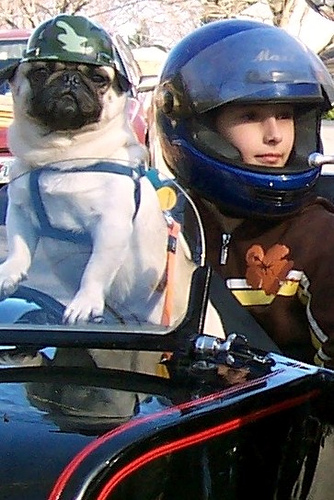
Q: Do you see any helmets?
A: Yes, there is a helmet.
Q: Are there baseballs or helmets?
A: Yes, there is a helmet.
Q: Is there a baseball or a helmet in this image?
A: Yes, there is a helmet.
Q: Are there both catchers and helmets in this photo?
A: No, there is a helmet but no catchers.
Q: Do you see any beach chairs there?
A: No, there are no beach chairs.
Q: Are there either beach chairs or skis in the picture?
A: No, there are no beach chairs or skis.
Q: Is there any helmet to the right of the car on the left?
A: Yes, there is a helmet to the right of the car.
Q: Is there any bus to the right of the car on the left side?
A: No, there is a helmet to the right of the car.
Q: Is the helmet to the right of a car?
A: Yes, the helmet is to the right of a car.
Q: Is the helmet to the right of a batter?
A: No, the helmet is to the right of a car.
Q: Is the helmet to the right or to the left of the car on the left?
A: The helmet is to the right of the car.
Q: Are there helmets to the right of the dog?
A: Yes, there is a helmet to the right of the dog.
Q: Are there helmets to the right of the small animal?
A: Yes, there is a helmet to the right of the dog.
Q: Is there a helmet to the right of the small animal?
A: Yes, there is a helmet to the right of the dog.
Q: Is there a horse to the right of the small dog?
A: No, there is a helmet to the right of the dog.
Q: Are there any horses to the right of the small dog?
A: No, there is a helmet to the right of the dog.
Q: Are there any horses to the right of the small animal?
A: No, there is a helmet to the right of the dog.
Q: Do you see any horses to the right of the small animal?
A: No, there is a helmet to the right of the dog.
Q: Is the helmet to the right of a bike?
A: No, the helmet is to the right of the dog.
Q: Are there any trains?
A: No, there are no trains.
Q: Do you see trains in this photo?
A: No, there are no trains.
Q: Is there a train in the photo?
A: No, there are no trains.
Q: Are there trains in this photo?
A: No, there are no trains.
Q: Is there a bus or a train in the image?
A: No, there are no trains or buses.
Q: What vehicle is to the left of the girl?
A: The vehicle is a car.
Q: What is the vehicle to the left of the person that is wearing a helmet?
A: The vehicle is a car.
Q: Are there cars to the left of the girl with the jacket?
A: Yes, there is a car to the left of the girl.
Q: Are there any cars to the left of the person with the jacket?
A: Yes, there is a car to the left of the girl.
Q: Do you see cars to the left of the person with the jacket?
A: Yes, there is a car to the left of the girl.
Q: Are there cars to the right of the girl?
A: No, the car is to the left of the girl.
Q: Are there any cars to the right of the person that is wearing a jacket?
A: No, the car is to the left of the girl.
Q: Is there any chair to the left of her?
A: No, there is a car to the left of the girl.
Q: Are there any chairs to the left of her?
A: No, there is a car to the left of the girl.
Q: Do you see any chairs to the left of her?
A: No, there is a car to the left of the girl.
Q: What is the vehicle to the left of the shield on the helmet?
A: The vehicle is a car.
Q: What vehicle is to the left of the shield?
A: The vehicle is a car.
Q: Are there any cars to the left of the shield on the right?
A: Yes, there is a car to the left of the shield.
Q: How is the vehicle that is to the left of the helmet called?
A: The vehicle is a car.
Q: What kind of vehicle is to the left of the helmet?
A: The vehicle is a car.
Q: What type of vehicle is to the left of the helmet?
A: The vehicle is a car.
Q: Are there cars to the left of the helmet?
A: Yes, there is a car to the left of the helmet.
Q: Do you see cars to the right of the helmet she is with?
A: No, the car is to the left of the helmet.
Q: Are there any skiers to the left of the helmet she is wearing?
A: No, there is a car to the left of the helmet.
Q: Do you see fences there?
A: No, there are no fences.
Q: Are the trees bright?
A: Yes, the trees are bright.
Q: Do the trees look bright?
A: Yes, the trees are bright.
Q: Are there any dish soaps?
A: No, there are no dish soaps.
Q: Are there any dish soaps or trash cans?
A: No, there are no dish soaps or trash cans.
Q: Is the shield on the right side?
A: Yes, the shield is on the right of the image.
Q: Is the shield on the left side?
A: No, the shield is on the right of the image.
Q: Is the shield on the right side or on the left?
A: The shield is on the right of the image.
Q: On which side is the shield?
A: The shield is on the right of the image.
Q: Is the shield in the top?
A: Yes, the shield is in the top of the image.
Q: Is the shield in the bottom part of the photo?
A: No, the shield is in the top of the image.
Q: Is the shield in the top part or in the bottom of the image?
A: The shield is in the top of the image.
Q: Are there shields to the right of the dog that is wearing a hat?
A: Yes, there is a shield to the right of the dog.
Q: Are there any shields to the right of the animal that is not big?
A: Yes, there is a shield to the right of the dog.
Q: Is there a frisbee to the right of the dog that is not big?
A: No, there is a shield to the right of the dog.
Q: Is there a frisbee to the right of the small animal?
A: No, there is a shield to the right of the dog.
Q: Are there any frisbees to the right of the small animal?
A: No, there is a shield to the right of the dog.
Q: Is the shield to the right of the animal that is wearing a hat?
A: Yes, the shield is to the right of the dog.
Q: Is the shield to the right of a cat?
A: No, the shield is to the right of the dog.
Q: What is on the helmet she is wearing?
A: The shield is on the helmet.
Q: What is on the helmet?
A: The shield is on the helmet.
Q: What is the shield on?
A: The shield is on the helmet.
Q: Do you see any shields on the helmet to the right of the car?
A: Yes, there is a shield on the helmet.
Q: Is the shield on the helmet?
A: Yes, the shield is on the helmet.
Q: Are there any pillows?
A: No, there are no pillows.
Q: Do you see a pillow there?
A: No, there are no pillows.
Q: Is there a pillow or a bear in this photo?
A: No, there are no pillows or bears.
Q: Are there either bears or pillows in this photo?
A: No, there are no pillows or bears.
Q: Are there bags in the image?
A: No, there are no bags.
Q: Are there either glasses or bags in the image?
A: No, there are no bags or glasses.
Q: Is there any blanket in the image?
A: No, there are no blankets.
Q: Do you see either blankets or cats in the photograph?
A: No, there are no blankets or cats.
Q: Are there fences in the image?
A: No, there are no fences.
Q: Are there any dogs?
A: Yes, there is a dog.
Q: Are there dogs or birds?
A: Yes, there is a dog.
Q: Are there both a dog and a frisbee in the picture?
A: No, there is a dog but no frisbees.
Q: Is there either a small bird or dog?
A: Yes, there is a small dog.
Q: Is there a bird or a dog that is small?
A: Yes, the dog is small.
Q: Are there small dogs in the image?
A: Yes, there is a small dog.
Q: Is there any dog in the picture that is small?
A: Yes, there is a dog that is small.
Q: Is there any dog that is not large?
A: Yes, there is a small dog.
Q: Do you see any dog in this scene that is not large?
A: Yes, there is a small dog.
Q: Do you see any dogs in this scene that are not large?
A: Yes, there is a small dog.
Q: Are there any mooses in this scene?
A: No, there are no mooses.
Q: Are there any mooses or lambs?
A: No, there are no mooses or lambs.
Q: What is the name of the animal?
A: The animal is a dog.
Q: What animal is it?
A: The animal is a dog.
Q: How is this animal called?
A: This is a dog.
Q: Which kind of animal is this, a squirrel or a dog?
A: This is a dog.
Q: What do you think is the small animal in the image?
A: The animal is a dog.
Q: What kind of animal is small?
A: The animal is a dog.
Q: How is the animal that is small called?
A: The animal is a dog.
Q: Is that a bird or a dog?
A: That is a dog.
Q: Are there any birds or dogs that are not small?
A: No, there is a dog but it is small.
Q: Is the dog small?
A: Yes, the dog is small.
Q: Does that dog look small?
A: Yes, the dog is small.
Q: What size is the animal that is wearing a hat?
A: The dog is small.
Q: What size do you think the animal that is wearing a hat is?
A: The dog is small.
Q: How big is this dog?
A: The dog is small.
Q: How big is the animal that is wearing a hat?
A: The dog is small.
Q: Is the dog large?
A: No, the dog is small.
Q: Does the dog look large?
A: No, the dog is small.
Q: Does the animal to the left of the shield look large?
A: No, the dog is small.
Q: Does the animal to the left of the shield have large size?
A: No, the dog is small.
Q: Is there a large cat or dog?
A: No, there is a dog but it is small.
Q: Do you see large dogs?
A: No, there is a dog but it is small.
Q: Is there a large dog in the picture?
A: No, there is a dog but it is small.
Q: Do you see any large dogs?
A: No, there is a dog but it is small.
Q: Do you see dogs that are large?
A: No, there is a dog but it is small.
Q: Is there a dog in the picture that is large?
A: No, there is a dog but it is small.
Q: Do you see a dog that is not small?
A: No, there is a dog but it is small.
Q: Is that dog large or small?
A: The dog is small.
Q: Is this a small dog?
A: Yes, this is a small dog.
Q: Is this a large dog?
A: No, this is a small dog.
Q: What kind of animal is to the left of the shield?
A: The animal is a dog.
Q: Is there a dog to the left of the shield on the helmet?
A: Yes, there is a dog to the left of the shield.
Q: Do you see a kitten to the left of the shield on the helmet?
A: No, there is a dog to the left of the shield.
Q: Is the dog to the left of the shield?
A: Yes, the dog is to the left of the shield.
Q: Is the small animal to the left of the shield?
A: Yes, the dog is to the left of the shield.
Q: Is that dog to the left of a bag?
A: No, the dog is to the left of the shield.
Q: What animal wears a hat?
A: The dog wears a hat.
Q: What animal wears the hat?
A: The dog wears a hat.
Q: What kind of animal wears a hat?
A: The animal is a dog.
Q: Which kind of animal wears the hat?
A: The animal is a dog.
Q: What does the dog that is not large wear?
A: The dog wears a hat.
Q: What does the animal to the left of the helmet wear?
A: The dog wears a hat.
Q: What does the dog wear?
A: The dog wears a hat.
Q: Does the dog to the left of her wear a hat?
A: Yes, the dog wears a hat.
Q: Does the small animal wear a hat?
A: Yes, the dog wears a hat.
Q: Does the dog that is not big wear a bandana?
A: No, the dog wears a hat.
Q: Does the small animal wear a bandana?
A: No, the dog wears a hat.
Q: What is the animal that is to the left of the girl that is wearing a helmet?
A: The animal is a dog.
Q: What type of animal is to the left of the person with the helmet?
A: The animal is a dog.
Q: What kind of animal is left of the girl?
A: The animal is a dog.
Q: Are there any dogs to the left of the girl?
A: Yes, there is a dog to the left of the girl.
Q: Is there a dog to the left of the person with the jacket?
A: Yes, there is a dog to the left of the girl.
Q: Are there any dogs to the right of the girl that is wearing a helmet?
A: No, the dog is to the left of the girl.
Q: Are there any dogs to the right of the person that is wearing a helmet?
A: No, the dog is to the left of the girl.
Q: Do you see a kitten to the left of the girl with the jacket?
A: No, there is a dog to the left of the girl.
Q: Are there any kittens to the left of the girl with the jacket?
A: No, there is a dog to the left of the girl.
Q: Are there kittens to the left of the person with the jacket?
A: No, there is a dog to the left of the girl.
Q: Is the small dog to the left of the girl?
A: Yes, the dog is to the left of the girl.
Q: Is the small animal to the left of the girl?
A: Yes, the dog is to the left of the girl.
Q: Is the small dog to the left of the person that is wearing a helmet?
A: Yes, the dog is to the left of the girl.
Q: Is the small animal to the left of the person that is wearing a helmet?
A: Yes, the dog is to the left of the girl.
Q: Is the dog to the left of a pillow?
A: No, the dog is to the left of the girl.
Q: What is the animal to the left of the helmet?
A: The animal is a dog.